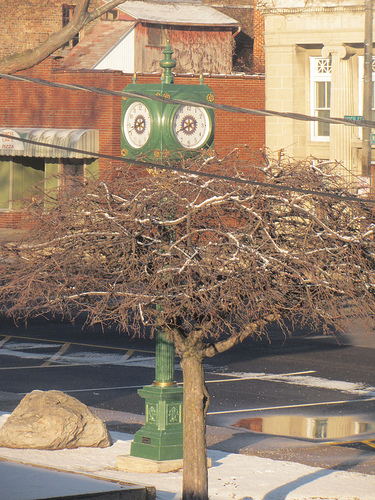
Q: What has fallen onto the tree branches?
A: Snow.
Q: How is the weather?
A: Clear.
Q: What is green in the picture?
A: A clock.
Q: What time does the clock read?
A: 9:40.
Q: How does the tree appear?
A: Bare.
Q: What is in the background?
A: Red building.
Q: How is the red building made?
A: Of brick.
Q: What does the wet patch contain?
A: Water.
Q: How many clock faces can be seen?
A: Two.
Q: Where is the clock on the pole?
A: The top.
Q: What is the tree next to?
A: Clock tower.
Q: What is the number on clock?
A: 5.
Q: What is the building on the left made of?
A: Bricks.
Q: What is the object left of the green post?
A: Boulder.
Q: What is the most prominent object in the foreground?
A: Tree.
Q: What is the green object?
A: A clock post.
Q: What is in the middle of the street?
A: Puddle.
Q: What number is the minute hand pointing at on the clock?
A: 8.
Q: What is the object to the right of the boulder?
A: A clock.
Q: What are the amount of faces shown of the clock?
A: 2.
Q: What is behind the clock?
A: A building.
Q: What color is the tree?
A: Brown.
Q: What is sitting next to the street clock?
A: A big rock.